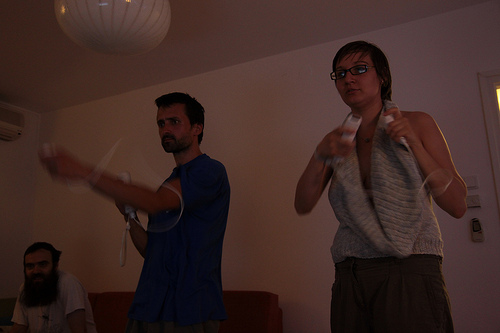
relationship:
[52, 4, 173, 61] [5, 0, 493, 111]
light fixture hanging from ceiling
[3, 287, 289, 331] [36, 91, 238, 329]
couch behind man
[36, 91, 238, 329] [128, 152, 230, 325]
man in shirt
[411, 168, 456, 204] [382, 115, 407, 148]
wire for white controllers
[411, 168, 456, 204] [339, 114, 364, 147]
wire for white controllers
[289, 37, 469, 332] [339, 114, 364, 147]
female holding white controllers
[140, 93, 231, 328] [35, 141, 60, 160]
man holding controller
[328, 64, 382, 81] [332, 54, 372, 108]
glasses on face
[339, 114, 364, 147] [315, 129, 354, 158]
white controllers in right hand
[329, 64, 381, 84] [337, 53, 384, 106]
glasses on face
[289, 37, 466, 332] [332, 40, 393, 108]
female has hair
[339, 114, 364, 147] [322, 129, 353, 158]
white controllers in right hand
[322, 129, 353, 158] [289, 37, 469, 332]
right hand of female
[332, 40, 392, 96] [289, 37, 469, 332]
hair on a female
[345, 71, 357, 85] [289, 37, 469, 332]
nose of a female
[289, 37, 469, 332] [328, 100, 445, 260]
female with sweater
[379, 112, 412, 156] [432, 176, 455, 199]
white controllers and wire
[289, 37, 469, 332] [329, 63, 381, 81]
female with glasses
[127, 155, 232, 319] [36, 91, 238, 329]
blue shirt on a man